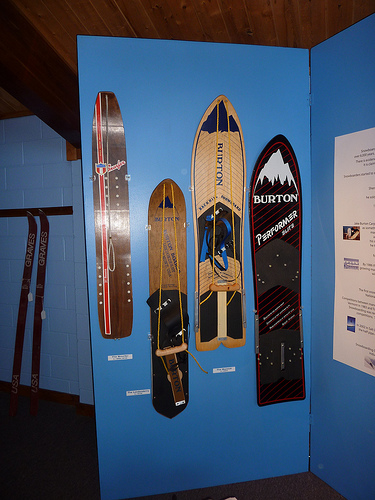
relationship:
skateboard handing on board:
[94, 92, 133, 338] [77, 13, 374, 499]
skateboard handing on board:
[150, 179, 188, 421] [77, 13, 374, 499]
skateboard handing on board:
[191, 96, 247, 351] [77, 13, 374, 499]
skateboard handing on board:
[250, 134, 305, 408] [77, 13, 374, 499]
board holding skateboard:
[77, 13, 374, 499] [94, 92, 133, 338]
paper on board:
[332, 124, 375, 377] [77, 13, 374, 499]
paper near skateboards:
[332, 124, 375, 377] [93, 89, 304, 418]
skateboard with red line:
[94, 92, 133, 338] [96, 92, 111, 345]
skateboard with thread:
[150, 179, 188, 421] [158, 184, 187, 368]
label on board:
[106, 355, 133, 363] [77, 13, 374, 499]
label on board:
[126, 388, 152, 398] [77, 13, 374, 499]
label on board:
[213, 365, 237, 375] [77, 13, 374, 499]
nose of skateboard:
[207, 91, 235, 107] [191, 96, 247, 351]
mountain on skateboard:
[254, 146, 303, 201] [250, 134, 305, 408]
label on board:
[107, 353, 133, 361] [77, 13, 374, 499]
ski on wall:
[10, 210, 50, 418] [1, 115, 96, 407]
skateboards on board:
[93, 89, 304, 418] [77, 13, 374, 499]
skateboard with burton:
[250, 134, 305, 408] [254, 194, 299, 204]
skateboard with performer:
[250, 134, 305, 408] [254, 210, 301, 250]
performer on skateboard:
[254, 210, 301, 250] [250, 134, 305, 408]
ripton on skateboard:
[218, 142, 226, 191] [191, 96, 247, 351]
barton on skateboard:
[158, 214, 183, 226] [150, 179, 188, 421]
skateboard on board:
[94, 92, 133, 338] [77, 13, 374, 499]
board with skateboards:
[77, 13, 374, 499] [93, 89, 304, 418]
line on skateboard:
[96, 92, 111, 345] [94, 92, 133, 338]